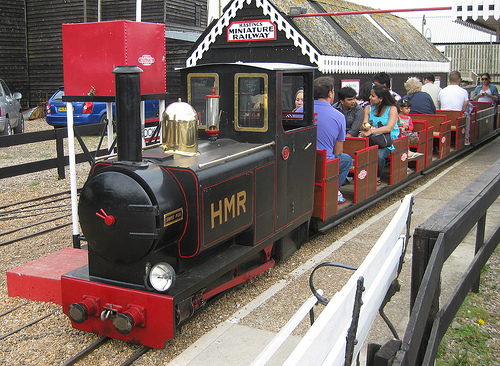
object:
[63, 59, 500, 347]
attraction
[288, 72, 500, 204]
people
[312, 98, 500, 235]
cars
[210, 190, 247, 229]
hmr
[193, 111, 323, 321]
side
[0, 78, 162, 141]
cars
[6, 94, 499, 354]
gravel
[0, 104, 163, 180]
fence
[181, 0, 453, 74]
roof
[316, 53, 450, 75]
detailing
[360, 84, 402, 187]
woman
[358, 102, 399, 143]
outfit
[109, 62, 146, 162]
smokestack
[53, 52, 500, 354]
train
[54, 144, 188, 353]
front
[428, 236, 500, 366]
grass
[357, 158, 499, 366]
fence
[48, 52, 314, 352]
engine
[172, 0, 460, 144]
building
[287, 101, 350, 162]
shirt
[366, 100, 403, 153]
shirt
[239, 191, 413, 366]
bench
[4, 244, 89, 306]
platform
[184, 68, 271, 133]
windows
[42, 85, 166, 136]
car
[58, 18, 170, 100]
box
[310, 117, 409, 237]
car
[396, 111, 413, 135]
shirt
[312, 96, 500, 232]
seats